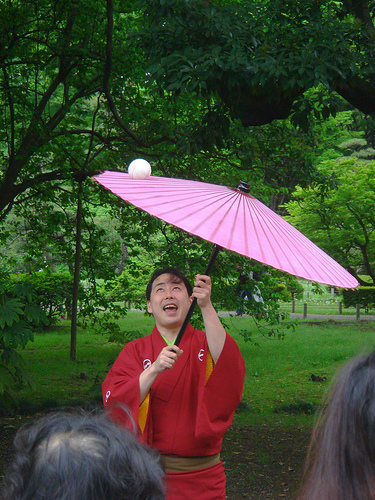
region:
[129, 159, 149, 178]
a baseball on top of the parasol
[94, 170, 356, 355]
a pink parasol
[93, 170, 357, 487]
a person in red holding a parasol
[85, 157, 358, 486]
man balancing a ball on an umbrella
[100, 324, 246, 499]
red outfit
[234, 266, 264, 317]
two people walking on the sidewalk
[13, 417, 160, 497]
man with a bald spot.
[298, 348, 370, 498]
woman with long brown hair in the audience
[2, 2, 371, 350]
several trees behind the performer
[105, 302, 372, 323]
a long sidewalk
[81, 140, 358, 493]
man with a parasol umbrella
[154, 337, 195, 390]
right hand of a man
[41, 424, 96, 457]
bald spot in hair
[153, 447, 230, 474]
brown sash on robe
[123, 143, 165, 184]
ball on an umbrella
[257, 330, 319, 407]
green grass on ground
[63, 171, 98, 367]
trunk of a tree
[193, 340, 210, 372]
design on red robe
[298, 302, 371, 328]
walkway in the park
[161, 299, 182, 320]
opened mouth of a man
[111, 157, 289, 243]
balancing a ball on top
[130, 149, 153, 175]
the ball is white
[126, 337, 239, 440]
his robe is red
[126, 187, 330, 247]
his umbrella is pink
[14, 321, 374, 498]
other people are watching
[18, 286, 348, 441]
the field is green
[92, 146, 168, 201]
the umbrella balances the ball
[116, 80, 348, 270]
there are many trees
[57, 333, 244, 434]
he wears a robe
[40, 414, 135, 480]
his head is balding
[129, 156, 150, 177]
The baseball is white.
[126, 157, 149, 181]
The baseball is round.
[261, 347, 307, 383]
The grass is green in color.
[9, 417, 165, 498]
The woman's hair is black.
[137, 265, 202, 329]
The man's hair is black.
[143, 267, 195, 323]
The man's hair is short.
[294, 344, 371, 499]
The woman's hair is brown.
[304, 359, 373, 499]
The woman's hair is long.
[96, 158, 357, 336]
The umbrella is pink.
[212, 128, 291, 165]
The leaves above the umbrella are green.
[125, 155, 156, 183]
Baseball on top of umbrella.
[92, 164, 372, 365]
Man holding umbrella.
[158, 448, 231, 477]
Beige belt karate man.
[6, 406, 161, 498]
Top of a man's head.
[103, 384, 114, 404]
White circle on man's robe.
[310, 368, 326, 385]
Black leaves in grass.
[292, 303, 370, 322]
Trail at a park.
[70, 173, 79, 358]
Tree without branches in the grass.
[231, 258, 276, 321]
People walking in the park.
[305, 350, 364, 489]
Side of a woman's head.